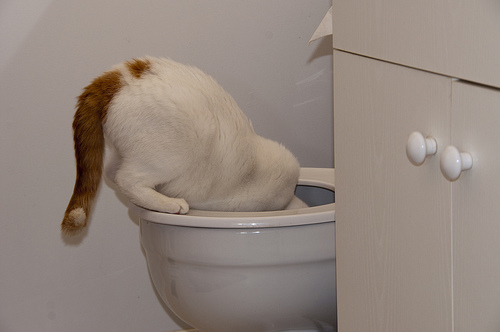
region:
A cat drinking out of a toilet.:
[62, 54, 341, 330]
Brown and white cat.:
[60, 55, 310, 247]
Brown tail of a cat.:
[59, 70, 124, 247]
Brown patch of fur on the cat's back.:
[125, 56, 155, 81]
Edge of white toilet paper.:
[307, 7, 334, 47]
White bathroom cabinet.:
[332, 1, 499, 331]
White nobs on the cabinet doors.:
[404, 127, 474, 179]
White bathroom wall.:
[0, 0, 331, 330]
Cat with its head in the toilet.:
[59, 56, 336, 330]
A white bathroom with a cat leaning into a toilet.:
[0, 0, 499, 330]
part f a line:
[433, 230, 460, 290]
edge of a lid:
[226, 182, 265, 232]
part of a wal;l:
[388, 258, 428, 328]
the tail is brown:
[59, 89, 111, 229]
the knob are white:
[396, 132, 471, 181]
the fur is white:
[121, 63, 303, 208]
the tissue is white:
[311, 16, 336, 39]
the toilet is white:
[141, 202, 331, 329]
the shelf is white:
[331, 7, 498, 330]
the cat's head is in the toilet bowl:
[285, 189, 336, 215]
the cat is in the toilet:
[60, 56, 317, 221]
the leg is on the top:
[117, 165, 188, 213]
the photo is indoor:
[9, 7, 474, 330]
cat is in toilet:
[100, 54, 310, 251]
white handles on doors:
[372, 100, 488, 187]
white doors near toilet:
[330, 48, 497, 293]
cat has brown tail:
[27, 79, 150, 254]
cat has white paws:
[111, 160, 188, 223]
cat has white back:
[158, 64, 306, 211]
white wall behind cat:
[0, 25, 147, 90]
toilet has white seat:
[165, 159, 351, 219]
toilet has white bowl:
[131, 160, 348, 315]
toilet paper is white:
[288, 7, 337, 51]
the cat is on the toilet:
[60, 53, 326, 224]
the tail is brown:
[56, 90, 125, 233]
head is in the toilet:
[255, 175, 346, 217]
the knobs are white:
[398, 128, 472, 178]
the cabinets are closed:
[331, 49, 491, 331]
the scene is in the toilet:
[6, 2, 497, 330]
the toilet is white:
[136, 202, 352, 331]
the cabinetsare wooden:
[333, 3, 495, 330]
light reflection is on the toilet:
[228, 209, 272, 244]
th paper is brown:
[308, 14, 331, 48]